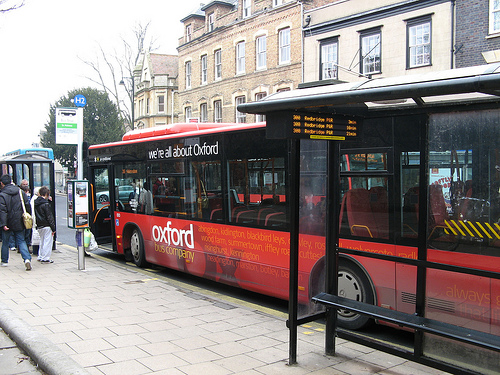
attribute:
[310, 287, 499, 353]
seat — black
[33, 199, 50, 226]
jacket — black 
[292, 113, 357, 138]
sign — electronic, destination sign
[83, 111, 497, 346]
bus — red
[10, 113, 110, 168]
sign — white, green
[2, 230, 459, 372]
sidewalk — TILED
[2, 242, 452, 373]
pavers — large, grey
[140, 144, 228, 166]
message — white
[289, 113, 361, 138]
words — yellow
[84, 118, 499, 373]
bus — red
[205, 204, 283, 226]
seats — inside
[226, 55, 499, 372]
shelter — public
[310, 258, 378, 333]
tire — rear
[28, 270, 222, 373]
walkway — paved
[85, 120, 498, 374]
side — red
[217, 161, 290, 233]
passenger window — bus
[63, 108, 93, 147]
sign — informational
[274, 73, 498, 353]
sheds — for people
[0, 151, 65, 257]
shelter — public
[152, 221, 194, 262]
writing — white, yellow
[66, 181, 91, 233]
sign — blue, white